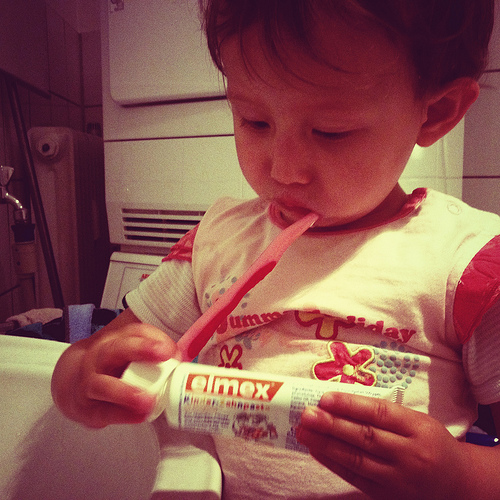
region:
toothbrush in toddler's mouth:
[168, 212, 323, 366]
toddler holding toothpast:
[117, 350, 402, 458]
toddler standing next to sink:
[1, 331, 223, 498]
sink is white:
[0, 332, 224, 499]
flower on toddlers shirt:
[314, 335, 374, 387]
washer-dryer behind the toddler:
[100, 0, 465, 315]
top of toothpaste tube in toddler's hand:
[52, 323, 172, 428]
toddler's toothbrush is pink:
[171, 211, 319, 359]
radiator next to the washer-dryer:
[20, 124, 90, 306]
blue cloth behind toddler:
[66, 303, 96, 340]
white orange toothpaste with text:
[121, 354, 401, 449]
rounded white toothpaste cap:
[113, 354, 173, 416]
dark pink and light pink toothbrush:
[172, 215, 325, 355]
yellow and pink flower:
[313, 338, 375, 385]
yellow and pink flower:
[216, 342, 246, 375]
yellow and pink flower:
[301, 309, 346, 339]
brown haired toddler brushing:
[57, 37, 499, 494]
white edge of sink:
[1, 333, 222, 495]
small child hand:
[301, 387, 473, 493]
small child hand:
[67, 325, 174, 420]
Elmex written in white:
[187, 373, 277, 402]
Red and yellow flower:
[302, 333, 384, 396]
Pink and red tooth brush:
[163, 208, 316, 405]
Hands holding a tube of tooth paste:
[108, 338, 413, 463]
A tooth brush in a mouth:
[151, 180, 336, 400]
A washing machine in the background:
[85, 1, 475, 356]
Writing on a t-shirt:
[205, 291, 420, 351]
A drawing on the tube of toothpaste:
[230, 410, 275, 440]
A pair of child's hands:
[71, 317, 453, 494]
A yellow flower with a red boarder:
[214, 344, 246, 371]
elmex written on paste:
[193, 367, 288, 407]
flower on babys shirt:
[313, 326, 394, 386]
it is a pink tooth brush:
[176, 215, 330, 372]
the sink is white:
[8, 335, 151, 495]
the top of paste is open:
[125, 360, 172, 433]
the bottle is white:
[141, 358, 403, 451]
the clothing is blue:
[21, 287, 106, 336]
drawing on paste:
[229, 413, 281, 443]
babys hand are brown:
[301, 394, 498, 491]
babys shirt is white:
[267, 276, 459, 498]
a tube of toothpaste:
[126, 349, 406, 451]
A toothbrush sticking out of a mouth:
[173, 192, 352, 357]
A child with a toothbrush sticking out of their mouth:
[183, 27, 480, 359]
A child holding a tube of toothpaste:
[69, 99, 496, 440]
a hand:
[286, 391, 458, 497]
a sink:
[1, 328, 216, 498]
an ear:
[416, 69, 486, 157]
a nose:
[269, 118, 313, 195]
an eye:
[293, 104, 386, 154]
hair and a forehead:
[185, 0, 492, 77]